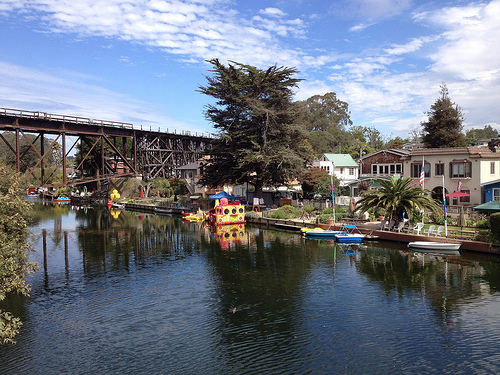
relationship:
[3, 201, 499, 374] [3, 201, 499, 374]
canal in canal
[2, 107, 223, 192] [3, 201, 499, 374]
bridge above canal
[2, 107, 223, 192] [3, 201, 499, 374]
bridge over canal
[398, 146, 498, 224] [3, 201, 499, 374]
building on canal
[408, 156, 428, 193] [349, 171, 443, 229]
flag behind palm tree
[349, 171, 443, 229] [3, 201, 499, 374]
palm tree by canal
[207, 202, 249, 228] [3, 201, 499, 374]
boat in canal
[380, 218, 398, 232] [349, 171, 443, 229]
chair under palm tree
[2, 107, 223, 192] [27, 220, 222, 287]
bridge has reflection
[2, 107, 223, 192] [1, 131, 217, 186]
bridge has substructure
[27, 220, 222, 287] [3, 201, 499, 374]
reflection in canal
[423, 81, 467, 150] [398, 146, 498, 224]
tree behind building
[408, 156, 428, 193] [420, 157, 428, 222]
flag on pole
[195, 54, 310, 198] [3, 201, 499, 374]
tree close to canal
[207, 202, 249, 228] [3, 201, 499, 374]
boat on canal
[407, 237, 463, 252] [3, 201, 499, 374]
boat on canal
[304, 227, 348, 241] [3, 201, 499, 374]
boat on canal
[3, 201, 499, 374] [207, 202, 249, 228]
canal has boat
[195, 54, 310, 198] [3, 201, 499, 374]
tree near canal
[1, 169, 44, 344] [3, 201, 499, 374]
tree near canal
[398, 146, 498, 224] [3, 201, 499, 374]
building near canal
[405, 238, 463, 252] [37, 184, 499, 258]
canoe on side of embankment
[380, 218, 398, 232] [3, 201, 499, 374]
chair faces canal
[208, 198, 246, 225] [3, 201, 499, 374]
toy on canal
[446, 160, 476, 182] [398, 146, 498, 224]
window on building